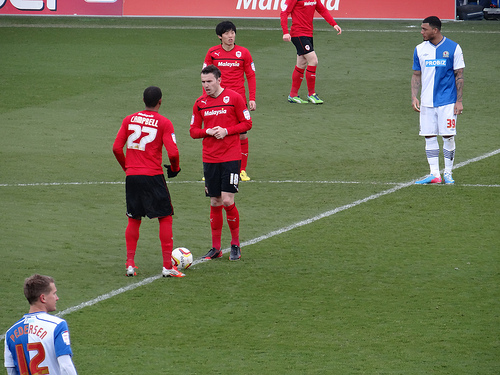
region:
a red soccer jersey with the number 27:
[113, 108, 180, 176]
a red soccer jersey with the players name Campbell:
[113, 109, 180, 174]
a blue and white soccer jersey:
[411, 37, 464, 107]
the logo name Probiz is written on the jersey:
[424, 58, 446, 66]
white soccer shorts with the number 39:
[419, 104, 456, 136]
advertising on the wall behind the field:
[1, 1, 456, 21]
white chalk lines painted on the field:
[1, 140, 498, 347]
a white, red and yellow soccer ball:
[171, 248, 193, 270]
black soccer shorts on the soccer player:
[125, 174, 173, 218]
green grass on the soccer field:
[81, 278, 499, 373]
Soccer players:
[98, 37, 270, 294]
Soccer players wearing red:
[105, 5, 270, 287]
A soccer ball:
[153, 217, 203, 294]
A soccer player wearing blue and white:
[407, 11, 484, 225]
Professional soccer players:
[95, 11, 495, 292]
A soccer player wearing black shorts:
[90, 62, 196, 302]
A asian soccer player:
[174, 17, 266, 196]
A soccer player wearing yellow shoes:
[186, 5, 270, 202]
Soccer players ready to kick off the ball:
[87, 20, 265, 293]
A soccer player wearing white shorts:
[388, 2, 485, 224]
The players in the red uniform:
[110, 0, 343, 282]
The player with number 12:
[4, 273, 85, 373]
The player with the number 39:
[405, 15, 471, 187]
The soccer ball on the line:
[170, 243, 198, 274]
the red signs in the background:
[1, 0, 458, 22]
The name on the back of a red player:
[129, 113, 161, 127]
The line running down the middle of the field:
[0, 148, 498, 350]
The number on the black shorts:
[228, 170, 243, 189]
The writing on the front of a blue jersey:
[422, 56, 450, 68]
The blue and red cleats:
[413, 172, 458, 189]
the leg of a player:
[121, 210, 138, 282]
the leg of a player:
[151, 209, 189, 282]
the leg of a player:
[221, 185, 246, 265]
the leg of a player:
[200, 193, 227, 274]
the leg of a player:
[440, 111, 460, 190]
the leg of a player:
[416, 120, 445, 188]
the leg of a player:
[301, 46, 327, 107]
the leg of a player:
[287, 50, 307, 106]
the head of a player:
[25, 270, 60, 311]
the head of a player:
[213, 16, 241, 50]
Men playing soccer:
[5, 5, 496, 317]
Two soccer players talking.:
[102, 50, 265, 279]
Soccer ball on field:
[157, 245, 221, 285]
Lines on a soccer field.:
[15, 126, 415, 328]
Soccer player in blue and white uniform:
[400, 9, 475, 198]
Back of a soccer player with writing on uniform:
[5, 304, 81, 372]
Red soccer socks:
[204, 197, 249, 258]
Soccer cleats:
[111, 242, 271, 284]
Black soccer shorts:
[198, 155, 247, 199]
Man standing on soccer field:
[182, 61, 262, 269]